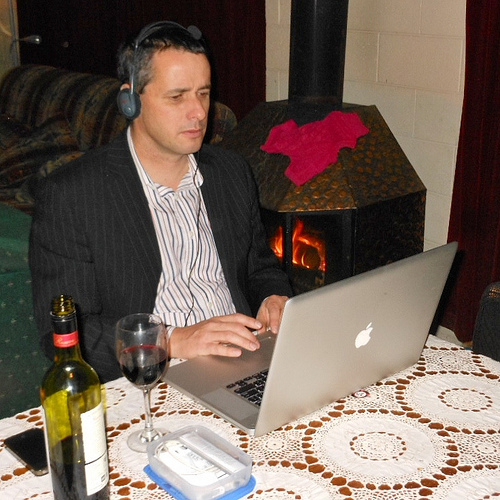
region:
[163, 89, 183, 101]
eye of the man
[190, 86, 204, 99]
eye of the man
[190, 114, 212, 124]
nose of the man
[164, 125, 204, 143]
mouth of the man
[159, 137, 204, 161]
chin of the man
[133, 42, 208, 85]
forehead of the man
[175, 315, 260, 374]
hand of the man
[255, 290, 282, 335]
hand of the man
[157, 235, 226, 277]
striped pattern on shirt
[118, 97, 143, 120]
headphone on the ear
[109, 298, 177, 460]
a glass of red wine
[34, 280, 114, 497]
a bottle of red wine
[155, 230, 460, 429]
a silver macbook pro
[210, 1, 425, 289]
a metal indoor fireplace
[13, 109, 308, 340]
a striped suit jacket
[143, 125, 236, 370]
a striped dress shirt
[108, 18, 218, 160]
headphones on a man's head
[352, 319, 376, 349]
a white apple logo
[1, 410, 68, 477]
a smart phone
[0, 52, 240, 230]
a couch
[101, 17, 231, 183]
head of the man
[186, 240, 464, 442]
laptop in front of man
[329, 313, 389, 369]
apple icon on laptop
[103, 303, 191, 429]
glass next to laptop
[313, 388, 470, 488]
white tablecloth on table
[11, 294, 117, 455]
wine bottle on table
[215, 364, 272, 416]
black keys on keyboard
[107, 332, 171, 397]
liquid in the glass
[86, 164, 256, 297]
light and dark outfit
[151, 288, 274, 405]
hand of the man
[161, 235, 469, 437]
apple laptop on a table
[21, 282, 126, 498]
bottle of wine on table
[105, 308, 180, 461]
glass of wine on table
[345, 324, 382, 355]
apple logo on laptop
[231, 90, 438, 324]
fireplace behind the man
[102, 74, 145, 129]
earphones on a man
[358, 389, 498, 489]
table cloth on a table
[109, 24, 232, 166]
face of a man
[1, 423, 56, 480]
phone on a table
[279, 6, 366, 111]
pipe to a fireplace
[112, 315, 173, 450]
a tall wine glass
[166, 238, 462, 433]
a gray laptop computer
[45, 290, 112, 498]
a large wine bottle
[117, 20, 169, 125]
black headphones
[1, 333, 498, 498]
a white tablecloth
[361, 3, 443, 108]
part of a brick wall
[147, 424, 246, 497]
a small clear plastic container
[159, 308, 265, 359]
the hand of a man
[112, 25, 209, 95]
a man's short cut black hair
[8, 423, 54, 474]
part of a cellphone